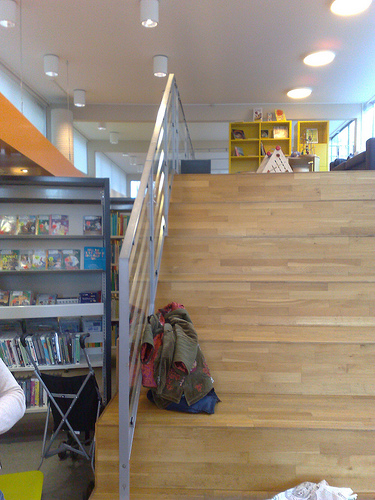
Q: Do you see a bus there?
A: No, there are no buses.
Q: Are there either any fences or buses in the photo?
A: No, there are no buses or fences.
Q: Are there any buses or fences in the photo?
A: No, there are no buses or fences.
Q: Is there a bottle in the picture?
A: No, there are no bottles.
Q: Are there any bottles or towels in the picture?
A: No, there are no bottles or towels.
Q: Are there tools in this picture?
A: No, there are no tools.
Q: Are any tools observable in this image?
A: No, there are no tools.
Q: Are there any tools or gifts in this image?
A: No, there are no tools or gifts.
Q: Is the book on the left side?
A: Yes, the book is on the left of the image.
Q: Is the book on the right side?
A: No, the book is on the left of the image.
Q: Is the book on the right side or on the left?
A: The book is on the left of the image.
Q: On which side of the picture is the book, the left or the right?
A: The book is on the left of the image.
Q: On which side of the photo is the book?
A: The book is on the left of the image.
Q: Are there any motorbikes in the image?
A: No, there are no motorbikes.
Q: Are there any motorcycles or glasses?
A: No, there are no motorcycles or glasses.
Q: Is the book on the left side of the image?
A: Yes, the book is on the left of the image.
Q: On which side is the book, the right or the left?
A: The book is on the left of the image.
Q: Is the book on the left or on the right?
A: The book is on the left of the image.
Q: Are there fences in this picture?
A: No, there are no fences.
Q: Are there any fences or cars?
A: No, there are no fences or cars.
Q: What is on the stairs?
A: The jacket is on the stairs.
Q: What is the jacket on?
A: The jacket is on the stairs.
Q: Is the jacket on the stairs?
A: Yes, the jacket is on the stairs.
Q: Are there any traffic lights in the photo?
A: No, there are no traffic lights.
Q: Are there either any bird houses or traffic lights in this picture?
A: No, there are no traffic lights or bird houses.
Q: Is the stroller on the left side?
A: Yes, the stroller is on the left of the image.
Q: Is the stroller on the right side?
A: No, the stroller is on the left of the image.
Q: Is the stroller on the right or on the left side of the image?
A: The stroller is on the left of the image.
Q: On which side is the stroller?
A: The stroller is on the left of the image.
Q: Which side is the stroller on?
A: The stroller is on the left of the image.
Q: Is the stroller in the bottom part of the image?
A: Yes, the stroller is in the bottom of the image.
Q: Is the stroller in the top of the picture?
A: No, the stroller is in the bottom of the image.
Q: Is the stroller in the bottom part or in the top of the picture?
A: The stroller is in the bottom of the image.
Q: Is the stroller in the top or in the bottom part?
A: The stroller is in the bottom of the image.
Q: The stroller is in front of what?
A: The stroller is in front of the shelf.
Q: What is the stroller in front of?
A: The stroller is in front of the shelf.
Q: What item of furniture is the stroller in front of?
A: The stroller is in front of the shelf.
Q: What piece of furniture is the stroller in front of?
A: The stroller is in front of the shelf.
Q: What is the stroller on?
A: The stroller is on the shelf.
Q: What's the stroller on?
A: The stroller is on the shelf.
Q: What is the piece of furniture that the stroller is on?
A: The piece of furniture is a shelf.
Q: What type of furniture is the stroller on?
A: The stroller is on the shelf.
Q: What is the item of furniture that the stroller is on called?
A: The piece of furniture is a shelf.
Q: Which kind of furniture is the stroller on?
A: The stroller is on the shelf.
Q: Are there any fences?
A: No, there are no fences.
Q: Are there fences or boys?
A: No, there are no fences or boys.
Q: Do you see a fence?
A: No, there are no fences.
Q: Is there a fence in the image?
A: No, there are no fences.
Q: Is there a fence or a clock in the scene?
A: No, there are no fences or clocks.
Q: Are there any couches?
A: Yes, there is a couch.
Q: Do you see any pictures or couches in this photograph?
A: Yes, there is a couch.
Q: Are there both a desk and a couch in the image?
A: No, there is a couch but no desks.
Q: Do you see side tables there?
A: No, there are no side tables.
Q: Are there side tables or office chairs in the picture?
A: No, there are no side tables or office chairs.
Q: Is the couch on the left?
A: No, the couch is on the right of the image.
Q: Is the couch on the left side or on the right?
A: The couch is on the right of the image.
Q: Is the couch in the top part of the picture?
A: Yes, the couch is in the top of the image.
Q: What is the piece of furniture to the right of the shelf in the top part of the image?
A: The piece of furniture is a couch.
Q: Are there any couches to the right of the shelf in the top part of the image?
A: Yes, there is a couch to the right of the shelf.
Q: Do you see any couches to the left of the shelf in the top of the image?
A: No, the couch is to the right of the shelf.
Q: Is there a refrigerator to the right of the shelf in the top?
A: No, there is a couch to the right of the shelf.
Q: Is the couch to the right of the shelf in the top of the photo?
A: Yes, the couch is to the right of the shelf.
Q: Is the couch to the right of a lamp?
A: No, the couch is to the right of the shelf.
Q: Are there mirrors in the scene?
A: No, there are no mirrors.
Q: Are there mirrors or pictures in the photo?
A: No, there are no mirrors or pictures.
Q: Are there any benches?
A: No, there are no benches.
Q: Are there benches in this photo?
A: No, there are no benches.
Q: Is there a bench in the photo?
A: No, there are no benches.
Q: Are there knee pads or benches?
A: No, there are no benches or knee pads.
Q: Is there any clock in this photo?
A: No, there are no clocks.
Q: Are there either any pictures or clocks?
A: No, there are no clocks or pictures.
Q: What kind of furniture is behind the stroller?
A: The piece of furniture is a shelf.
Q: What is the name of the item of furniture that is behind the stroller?
A: The piece of furniture is a shelf.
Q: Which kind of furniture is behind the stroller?
A: The piece of furniture is a shelf.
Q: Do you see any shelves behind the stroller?
A: Yes, there is a shelf behind the stroller.